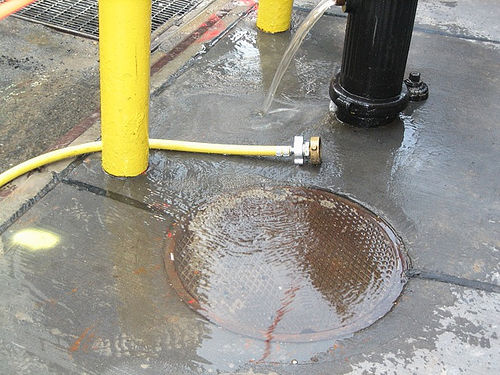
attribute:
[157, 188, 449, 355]
manhole — water-covered, brown, watery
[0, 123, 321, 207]
hose — yellow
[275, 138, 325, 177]
connector — metal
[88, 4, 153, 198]
pole — yellow, metal, for light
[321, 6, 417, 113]
hydrant — black, open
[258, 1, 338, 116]
water — on ground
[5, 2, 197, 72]
grate — metal, on street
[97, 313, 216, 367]
footprint — on ground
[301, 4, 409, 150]
pole — black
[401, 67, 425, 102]
bolt — black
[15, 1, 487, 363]
sidewalk — wet, cement, watery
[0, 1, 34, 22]
wire — orange